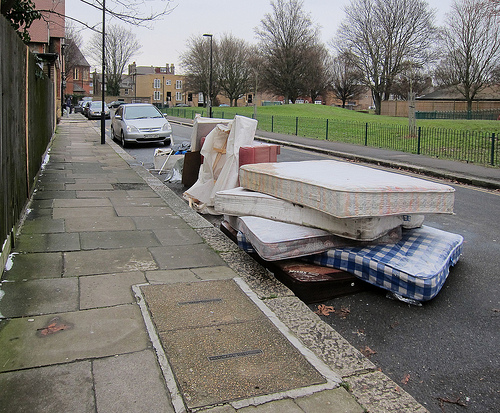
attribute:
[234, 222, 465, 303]
mattress — blue, white, checkered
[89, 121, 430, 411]
curb — wide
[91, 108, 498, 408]
road — grey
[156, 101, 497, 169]
fence — iron, long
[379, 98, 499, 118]
fence — wooden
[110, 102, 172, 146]
car — parked, white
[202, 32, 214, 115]
street light — black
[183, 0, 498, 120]
trees — leafless, bare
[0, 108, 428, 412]
sidewalk — weathered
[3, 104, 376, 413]
slabs — irregular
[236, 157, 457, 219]
mattress — white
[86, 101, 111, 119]
car — parked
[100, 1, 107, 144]
pole — dark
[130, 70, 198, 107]
building — orange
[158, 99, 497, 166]
grass — green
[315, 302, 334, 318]
leaf — dry